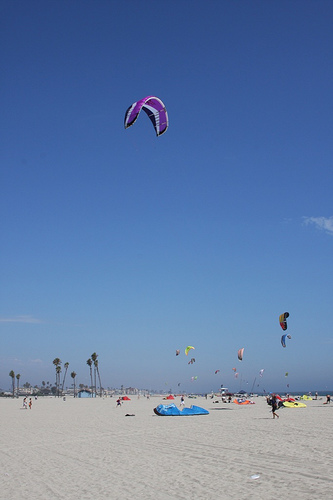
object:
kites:
[231, 367, 236, 372]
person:
[179, 395, 186, 408]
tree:
[91, 352, 103, 398]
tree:
[86, 358, 93, 398]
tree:
[70, 371, 77, 398]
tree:
[9, 370, 16, 398]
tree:
[52, 356, 62, 397]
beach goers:
[201, 389, 329, 422]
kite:
[184, 345, 195, 356]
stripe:
[125, 101, 160, 135]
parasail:
[280, 332, 291, 347]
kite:
[123, 95, 169, 138]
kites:
[237, 347, 245, 361]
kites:
[191, 357, 196, 365]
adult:
[23, 397, 29, 410]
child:
[29, 397, 33, 409]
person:
[116, 397, 122, 409]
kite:
[122, 396, 131, 401]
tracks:
[57, 430, 332, 500]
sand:
[0, 392, 333, 499]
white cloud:
[279, 214, 331, 235]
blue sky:
[0, 0, 332, 396]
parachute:
[278, 311, 289, 330]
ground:
[252, 458, 258, 476]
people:
[269, 396, 280, 419]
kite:
[278, 311, 290, 331]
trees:
[55, 365, 62, 397]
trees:
[52, 357, 61, 399]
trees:
[42, 380, 46, 390]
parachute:
[123, 95, 169, 138]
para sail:
[123, 95, 169, 137]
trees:
[59, 361, 70, 397]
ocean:
[256, 390, 332, 396]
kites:
[178, 383, 181, 387]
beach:
[0, 392, 333, 499]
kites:
[259, 368, 266, 378]